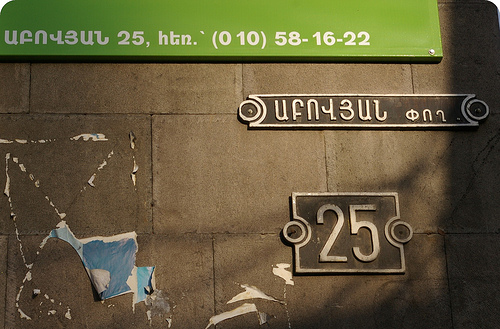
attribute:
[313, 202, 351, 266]
number — white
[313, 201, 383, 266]
number — 25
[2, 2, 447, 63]
sign — green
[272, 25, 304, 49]
58 — white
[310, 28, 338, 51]
16 — white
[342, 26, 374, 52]
22 — white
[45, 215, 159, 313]
paper — blue, ripped, remnants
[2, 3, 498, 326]
wall — grey, block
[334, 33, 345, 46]
- — small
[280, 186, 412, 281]
sign — black, silver, rectangular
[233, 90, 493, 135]
sign — long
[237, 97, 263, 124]
circle — small